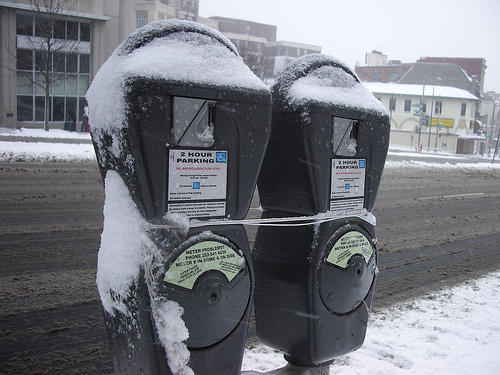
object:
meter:
[82, 17, 274, 374]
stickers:
[193, 182, 202, 190]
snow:
[85, 164, 200, 375]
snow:
[271, 51, 391, 114]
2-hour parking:
[176, 151, 215, 164]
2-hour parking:
[336, 160, 359, 170]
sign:
[424, 118, 454, 127]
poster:
[330, 114, 365, 156]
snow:
[171, 266, 500, 375]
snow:
[79, 14, 269, 133]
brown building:
[0, 1, 135, 133]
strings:
[151, 213, 357, 230]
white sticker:
[167, 201, 228, 219]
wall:
[0, 9, 19, 130]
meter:
[243, 50, 394, 375]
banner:
[423, 117, 454, 128]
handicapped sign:
[358, 160, 367, 169]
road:
[0, 150, 500, 374]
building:
[354, 62, 477, 137]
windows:
[16, 94, 34, 123]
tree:
[0, 0, 89, 134]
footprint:
[365, 346, 416, 372]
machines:
[81, 18, 282, 375]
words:
[179, 151, 213, 157]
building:
[354, 81, 480, 154]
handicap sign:
[215, 151, 227, 164]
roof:
[355, 63, 480, 96]